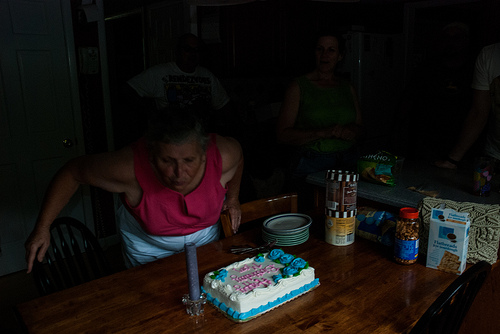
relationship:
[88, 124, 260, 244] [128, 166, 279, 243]
woman in top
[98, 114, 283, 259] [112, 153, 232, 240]
person in shirt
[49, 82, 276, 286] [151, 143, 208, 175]
woman has eyes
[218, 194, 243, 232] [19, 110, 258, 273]
left hand of old woman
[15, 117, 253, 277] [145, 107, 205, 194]
woman has head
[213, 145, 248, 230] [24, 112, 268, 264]
arm of woman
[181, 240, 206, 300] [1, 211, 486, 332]
candle on table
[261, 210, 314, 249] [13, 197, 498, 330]
plates on table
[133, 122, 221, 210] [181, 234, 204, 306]
woman blew out candle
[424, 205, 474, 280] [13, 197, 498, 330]
box on table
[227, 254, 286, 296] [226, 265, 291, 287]
writing on cake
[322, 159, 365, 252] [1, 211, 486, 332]
icecream on table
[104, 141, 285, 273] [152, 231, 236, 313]
woman blowing out candle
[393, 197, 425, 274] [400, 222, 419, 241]
jar are of nuts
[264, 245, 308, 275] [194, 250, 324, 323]
flowers are on cake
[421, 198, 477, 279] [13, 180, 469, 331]
box on top of table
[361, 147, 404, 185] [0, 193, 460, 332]
bag on top of table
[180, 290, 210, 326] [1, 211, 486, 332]
holder on table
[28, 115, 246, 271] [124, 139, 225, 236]
woman wearing shirt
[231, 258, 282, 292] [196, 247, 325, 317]
pink letters are on cake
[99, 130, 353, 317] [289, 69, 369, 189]
woman wearing top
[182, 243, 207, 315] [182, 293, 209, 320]
candle in glass holder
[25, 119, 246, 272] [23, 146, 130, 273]
old woman has arm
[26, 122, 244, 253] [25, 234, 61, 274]
woman has hand